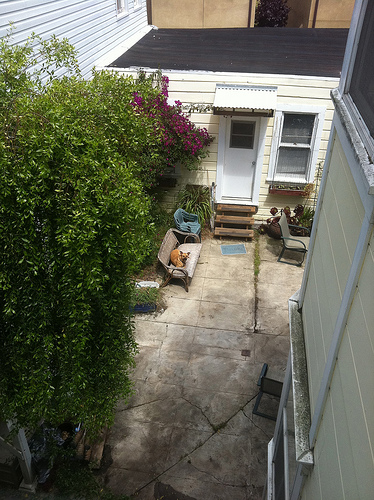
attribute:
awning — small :
[211, 81, 279, 112]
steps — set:
[211, 198, 259, 248]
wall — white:
[317, 347, 372, 487]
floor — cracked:
[180, 384, 252, 460]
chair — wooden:
[247, 353, 286, 416]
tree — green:
[40, 327, 90, 367]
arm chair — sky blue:
[173, 207, 202, 238]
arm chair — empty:
[280, 217, 310, 263]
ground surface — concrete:
[126, 223, 279, 497]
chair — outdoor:
[256, 363, 283, 423]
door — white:
[204, 114, 261, 208]